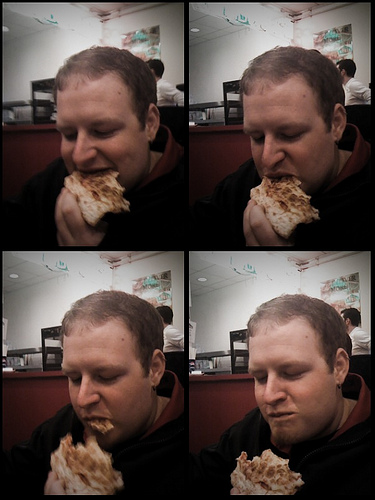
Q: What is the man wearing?
A: A jacket.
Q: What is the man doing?
A: Eating.